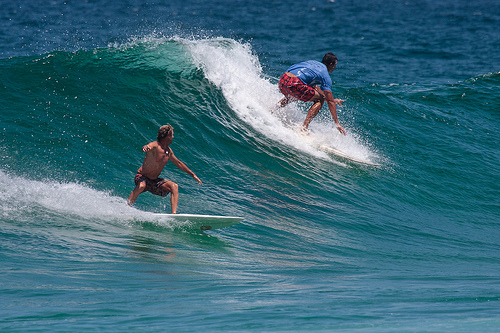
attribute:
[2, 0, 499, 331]
water — blue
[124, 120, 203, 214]
man — reaching, surfing, shirtless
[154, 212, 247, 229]
surfboard — white, long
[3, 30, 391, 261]
wave — forming a tube, breaking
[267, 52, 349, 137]
surfer — goofy footed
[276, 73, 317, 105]
bathing suit — red, black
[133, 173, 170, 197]
shorts — dark colored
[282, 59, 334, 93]
tshirt — blue, soaking wet